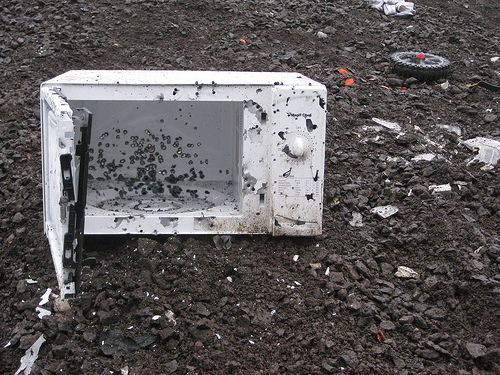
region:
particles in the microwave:
[92, 130, 199, 195]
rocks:
[299, 274, 384, 326]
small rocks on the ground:
[211, 289, 328, 349]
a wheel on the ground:
[389, 38, 446, 78]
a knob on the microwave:
[284, 135, 311, 158]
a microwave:
[28, 68, 333, 249]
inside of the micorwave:
[136, 112, 205, 139]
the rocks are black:
[161, 287, 321, 357]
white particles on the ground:
[374, 112, 484, 175]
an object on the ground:
[373, 3, 416, 15]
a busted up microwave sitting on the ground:
[36, 66, 325, 286]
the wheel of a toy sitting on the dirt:
[388, 45, 448, 73]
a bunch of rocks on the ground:
[345, 262, 457, 363]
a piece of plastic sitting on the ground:
[457, 131, 498, 167]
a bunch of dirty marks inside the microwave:
[103, 122, 219, 187]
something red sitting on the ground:
[340, 65, 353, 86]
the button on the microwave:
[282, 132, 312, 164]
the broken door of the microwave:
[27, 85, 92, 287]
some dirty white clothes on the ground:
[374, 0, 417, 18]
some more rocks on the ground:
[460, 230, 498, 293]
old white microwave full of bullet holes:
[42, 68, 326, 300]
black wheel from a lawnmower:
[392, 46, 448, 78]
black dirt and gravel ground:
[5, 4, 495, 369]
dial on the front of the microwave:
[285, 135, 314, 164]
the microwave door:
[41, 95, 84, 299]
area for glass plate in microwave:
[103, 195, 206, 212]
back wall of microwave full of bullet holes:
[90, 130, 210, 196]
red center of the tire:
[413, 51, 424, 61]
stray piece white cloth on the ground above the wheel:
[382, 1, 417, 17]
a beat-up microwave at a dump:
[37, 64, 327, 301]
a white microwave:
[27, 68, 327, 298]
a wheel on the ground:
[390, 48, 451, 73]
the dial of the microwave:
[283, 129, 313, 158]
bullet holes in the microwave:
[103, 128, 205, 188]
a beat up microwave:
[33, 63, 332, 300]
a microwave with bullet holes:
[26, 68, 327, 278]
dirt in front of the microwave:
[90, 244, 498, 371]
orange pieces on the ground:
[333, 63, 391, 97]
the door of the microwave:
[27, 85, 90, 300]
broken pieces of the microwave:
[341, 108, 498, 283]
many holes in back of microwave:
[81, 123, 241, 230]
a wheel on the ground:
[383, 24, 485, 101]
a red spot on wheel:
[415, 45, 426, 58]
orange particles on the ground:
[269, 45, 411, 104]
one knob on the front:
[276, 120, 316, 165]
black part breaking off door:
[38, 86, 116, 308]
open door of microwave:
[23, 56, 145, 323]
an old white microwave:
[24, 48, 374, 343]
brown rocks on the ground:
[69, 153, 499, 374]